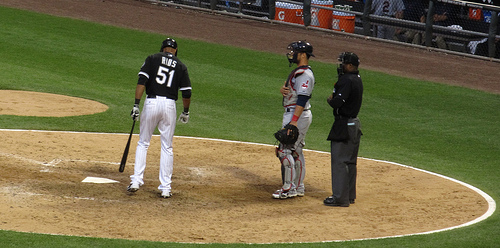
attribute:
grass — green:
[3, 21, 121, 90]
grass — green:
[363, 79, 498, 161]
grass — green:
[0, 2, 496, 246]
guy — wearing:
[119, 39, 192, 201]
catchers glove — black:
[275, 125, 299, 152]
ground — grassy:
[380, 123, 412, 153]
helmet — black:
[287, 38, 314, 55]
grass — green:
[41, 33, 98, 72]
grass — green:
[208, 59, 261, 125]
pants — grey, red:
[275, 105, 312, 189]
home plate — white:
[81, 170, 121, 188]